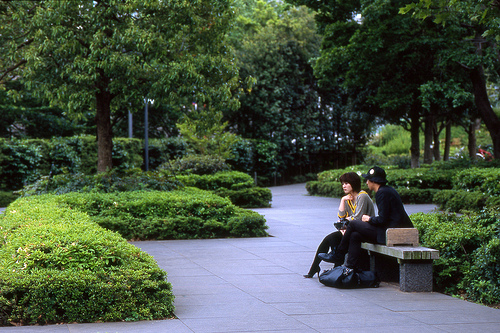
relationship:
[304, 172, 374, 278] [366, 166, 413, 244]
woman with man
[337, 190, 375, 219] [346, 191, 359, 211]
gray sweater with yellow trim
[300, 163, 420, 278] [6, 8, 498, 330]
man and woman in park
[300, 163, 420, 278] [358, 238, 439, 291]
man and woman sit on stone bench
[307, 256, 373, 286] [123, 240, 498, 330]
black bag on cement sidewalk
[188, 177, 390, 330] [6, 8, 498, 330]
cement walkway leads through park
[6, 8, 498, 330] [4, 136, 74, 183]
park has lush bush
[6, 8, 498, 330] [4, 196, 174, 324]
park has lush bush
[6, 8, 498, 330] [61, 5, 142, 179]
park has tree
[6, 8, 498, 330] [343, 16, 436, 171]
park has tree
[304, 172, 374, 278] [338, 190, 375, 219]
woman wears gray sweater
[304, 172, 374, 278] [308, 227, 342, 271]
woman wears black pants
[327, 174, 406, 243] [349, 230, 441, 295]
people on bench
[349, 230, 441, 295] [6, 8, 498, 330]
bench in park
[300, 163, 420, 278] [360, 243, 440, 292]
man and woman on bench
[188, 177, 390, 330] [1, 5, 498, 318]
cement walkway curves through landscaping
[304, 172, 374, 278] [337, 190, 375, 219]
woman wearing gray sweater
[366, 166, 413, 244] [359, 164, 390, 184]
man wearing black hat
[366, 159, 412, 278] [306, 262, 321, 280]
man wearing black shoes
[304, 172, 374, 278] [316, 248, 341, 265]
woman wearing black shoes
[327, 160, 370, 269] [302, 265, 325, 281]
woman wearing high-heeled shoe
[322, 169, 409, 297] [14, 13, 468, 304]
two people sitting in park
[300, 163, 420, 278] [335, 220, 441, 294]
man and woman sitting in bench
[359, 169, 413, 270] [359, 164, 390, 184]
person wearing black hat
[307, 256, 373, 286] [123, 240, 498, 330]
black bag lays on cement sidewalk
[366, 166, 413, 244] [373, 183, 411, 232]
man wearing a black shirt